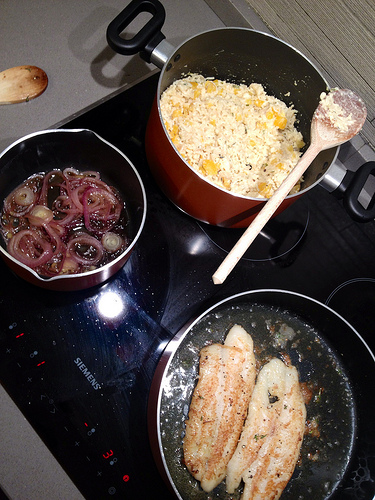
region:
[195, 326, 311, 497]
the cutlets are being fried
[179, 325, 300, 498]
the cutlets are brown on top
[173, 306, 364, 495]
the pan is full of oil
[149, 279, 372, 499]
the pan is made of metal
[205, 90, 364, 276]
the spoon is made of wood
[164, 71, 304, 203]
the pot is holding rice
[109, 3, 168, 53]
the handles are made of plastic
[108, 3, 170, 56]
the handles are black in color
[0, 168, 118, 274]
onions are in the pot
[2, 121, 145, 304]
the pot is made of metal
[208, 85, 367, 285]
Wooden cooking spoon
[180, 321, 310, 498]
Two pieces of fried fish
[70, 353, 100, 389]
Brand name "Siemens" on a stovetop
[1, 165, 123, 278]
Sliced and fried red onions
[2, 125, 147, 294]
Red cooking pot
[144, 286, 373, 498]
Red frying pan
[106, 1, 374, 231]
Red double-handled large cooking pot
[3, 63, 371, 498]
Flameless stove top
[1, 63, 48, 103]
Serving end of a wooden spoon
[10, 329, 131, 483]
Red lit up numbers on a stovetop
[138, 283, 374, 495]
skillet of frying food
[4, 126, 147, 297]
Pot of simmering food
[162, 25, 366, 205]
Pot of cooked rice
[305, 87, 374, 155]
Part of wooden spoon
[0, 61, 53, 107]
Part of wooden spoon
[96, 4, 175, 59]
Handle of cook pot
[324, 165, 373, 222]
Handle of cook pot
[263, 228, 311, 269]
Part of stove burner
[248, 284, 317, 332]
Part of dark skillet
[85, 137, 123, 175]
Part of black cooking pot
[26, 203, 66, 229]
pot of sauteed onions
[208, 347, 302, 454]
2 fish in frying pan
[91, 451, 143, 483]
number 3 on range top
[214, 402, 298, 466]
fish is seasoned and oily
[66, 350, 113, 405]
the word siemens on range top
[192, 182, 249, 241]
big red pot of whatever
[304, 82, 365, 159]
wooden spoon on red pot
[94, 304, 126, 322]
light reflecting off range top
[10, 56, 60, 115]
wooden spoon on counter top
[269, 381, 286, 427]
green herbs on fish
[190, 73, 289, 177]
rice in a pot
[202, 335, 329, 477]
fish in a pan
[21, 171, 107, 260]
onions in a pan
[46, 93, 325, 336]
food being prepared on the stove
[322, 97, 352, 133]
rice on a wooden spoon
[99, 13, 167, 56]
black handle on a pot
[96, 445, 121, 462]
number 3 on a stove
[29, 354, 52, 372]
number 1 on a stove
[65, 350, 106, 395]
siemens on a stove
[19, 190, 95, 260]
onions cooking in oil